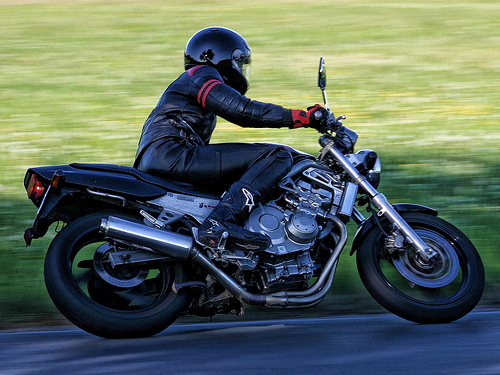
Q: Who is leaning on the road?
A: Person riding a motorcycle.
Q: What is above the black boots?
A: A pair of black leather pants.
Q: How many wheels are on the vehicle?
A: 2.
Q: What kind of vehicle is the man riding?
A: A motorcycle.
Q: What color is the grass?
A: Green.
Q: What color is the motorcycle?
A: Black and silver.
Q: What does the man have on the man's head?
A: A helmet.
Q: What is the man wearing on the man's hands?
A: Gloves.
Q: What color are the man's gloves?
A: Red and black.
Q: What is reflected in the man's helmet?
A: A tree.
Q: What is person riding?
A: Motorcycle.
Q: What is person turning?
A: Motorcycle.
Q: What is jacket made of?
A: Leather.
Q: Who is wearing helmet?
A: Motorcyclist.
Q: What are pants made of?
A: Leather.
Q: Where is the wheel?
A: On motorcycle.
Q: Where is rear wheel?
A: Motorcycle.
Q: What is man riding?
A: Motorcycle.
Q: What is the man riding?
A: A motorcycle.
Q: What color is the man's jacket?
A: Black.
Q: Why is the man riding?
A: To travel quickly.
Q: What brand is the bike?
A: Harley-Davidson.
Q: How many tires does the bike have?
A: Two.